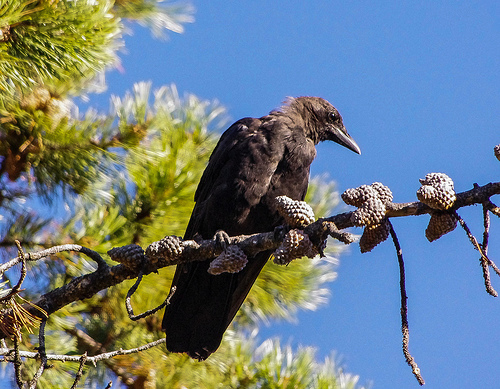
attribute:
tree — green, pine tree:
[1, 1, 496, 387]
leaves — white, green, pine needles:
[3, 1, 378, 387]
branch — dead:
[4, 181, 498, 343]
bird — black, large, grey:
[161, 95, 362, 361]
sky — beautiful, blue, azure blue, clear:
[1, 0, 499, 388]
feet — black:
[210, 222, 294, 253]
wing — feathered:
[160, 117, 308, 360]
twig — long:
[386, 217, 426, 385]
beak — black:
[328, 126, 363, 154]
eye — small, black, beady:
[329, 111, 340, 121]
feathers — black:
[157, 116, 308, 361]